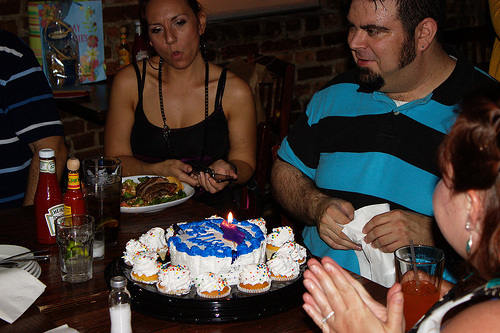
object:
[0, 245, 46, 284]
white plates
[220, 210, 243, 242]
candle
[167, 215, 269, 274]
cake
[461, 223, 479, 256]
earring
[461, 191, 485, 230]
ear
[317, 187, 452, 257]
hands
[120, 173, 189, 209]
food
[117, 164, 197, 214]
plate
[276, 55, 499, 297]
shirt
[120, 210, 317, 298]
cupcakes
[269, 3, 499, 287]
man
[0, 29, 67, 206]
man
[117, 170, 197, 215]
plate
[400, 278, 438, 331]
soda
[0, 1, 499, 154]
ground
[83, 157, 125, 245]
glass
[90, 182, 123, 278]
drink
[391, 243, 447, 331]
glass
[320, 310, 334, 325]
ring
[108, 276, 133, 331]
salt shaker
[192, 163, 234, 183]
cellphone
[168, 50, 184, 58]
mouth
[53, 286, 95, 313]
table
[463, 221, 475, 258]
silver earrings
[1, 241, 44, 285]
plates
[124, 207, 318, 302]
cupcakes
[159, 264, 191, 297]
sprinkles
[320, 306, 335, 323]
ring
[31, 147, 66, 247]
bottle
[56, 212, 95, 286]
juice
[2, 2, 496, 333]
family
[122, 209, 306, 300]
birthday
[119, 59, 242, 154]
top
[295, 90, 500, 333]
woman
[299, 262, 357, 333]
finger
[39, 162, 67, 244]
ketchup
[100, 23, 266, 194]
woman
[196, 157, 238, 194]
hand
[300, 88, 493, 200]
black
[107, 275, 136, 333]
clear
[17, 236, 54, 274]
stack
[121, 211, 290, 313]
sprinkles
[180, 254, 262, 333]
frosting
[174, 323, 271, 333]
wood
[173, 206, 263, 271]
birthday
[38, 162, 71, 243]
ketchup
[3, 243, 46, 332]
stack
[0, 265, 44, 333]
napkin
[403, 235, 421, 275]
straw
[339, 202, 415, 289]
napkin